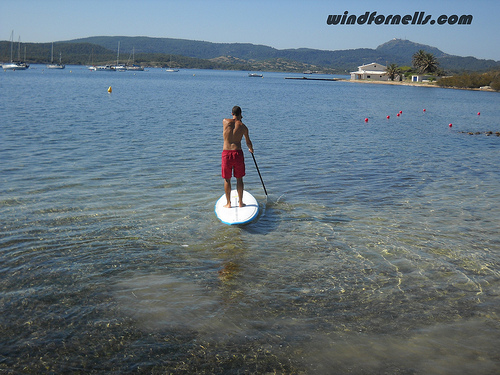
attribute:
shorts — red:
[215, 146, 249, 184]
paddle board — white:
[213, 187, 257, 224]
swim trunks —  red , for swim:
[217, 150, 244, 180]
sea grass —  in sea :
[12, 201, 495, 368]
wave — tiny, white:
[378, 239, 405, 299]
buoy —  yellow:
[106, 82, 112, 94]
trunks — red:
[216, 149, 250, 181]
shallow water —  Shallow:
[5, 235, 499, 373]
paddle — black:
[248, 146, 273, 205]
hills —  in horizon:
[122, 29, 331, 99]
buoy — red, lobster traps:
[357, 115, 368, 121]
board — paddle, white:
[195, 183, 289, 261]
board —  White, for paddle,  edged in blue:
[221, 184, 311, 265]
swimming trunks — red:
[217, 147, 251, 182]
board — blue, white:
[213, 118, 276, 245]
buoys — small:
[364, 102, 498, 146]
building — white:
[347, 62, 391, 80]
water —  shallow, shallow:
[0, 62, 495, 371]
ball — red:
[364, 117, 369, 123]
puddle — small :
[106, 263, 233, 342]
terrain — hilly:
[0, 35, 500, 85]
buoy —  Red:
[357, 112, 369, 128]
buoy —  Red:
[385, 114, 390, 123]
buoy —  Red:
[448, 122, 454, 129]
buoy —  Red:
[474, 110, 484, 120]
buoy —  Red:
[420, 107, 426, 114]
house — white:
[350, 60, 390, 81]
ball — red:
[363, 115, 370, 124]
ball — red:
[384, 114, 393, 122]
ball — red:
[446, 120, 457, 134]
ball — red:
[422, 106, 428, 113]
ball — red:
[475, 110, 483, 117]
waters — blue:
[273, 97, 359, 184]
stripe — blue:
[217, 211, 244, 227]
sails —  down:
[49, 32, 58, 63]